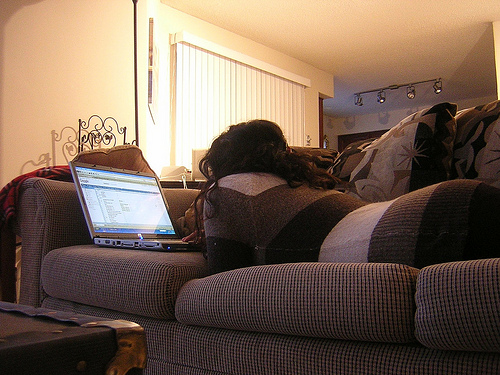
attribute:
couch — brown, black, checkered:
[150, 170, 478, 326]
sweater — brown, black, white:
[206, 115, 481, 272]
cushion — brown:
[40, 242, 208, 319]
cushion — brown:
[174, 262, 420, 342]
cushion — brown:
[413, 257, 498, 352]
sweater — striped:
[207, 180, 477, 257]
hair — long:
[179, 123, 326, 203]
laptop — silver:
[68, 159, 201, 252]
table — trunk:
[0, 294, 165, 374]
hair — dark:
[201, 117, 330, 183]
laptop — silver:
[65, 157, 217, 264]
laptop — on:
[62, 156, 209, 255]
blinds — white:
[168, 30, 312, 171]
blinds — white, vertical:
[169, 35, 310, 180]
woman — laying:
[196, 116, 488, 275]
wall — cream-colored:
[3, 1, 334, 304]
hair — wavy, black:
[198, 118, 341, 213]